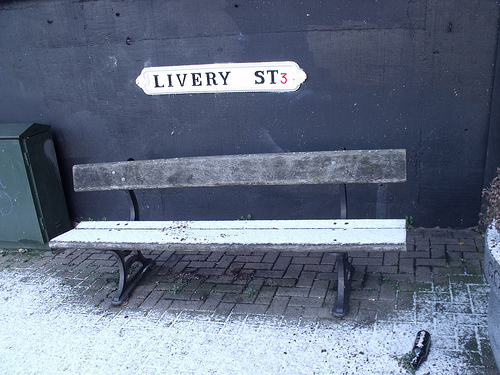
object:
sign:
[134, 59, 308, 97]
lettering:
[150, 68, 233, 90]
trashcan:
[2, 119, 72, 244]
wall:
[0, 2, 497, 240]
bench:
[47, 144, 413, 317]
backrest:
[66, 143, 413, 195]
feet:
[106, 256, 357, 321]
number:
[278, 70, 290, 90]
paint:
[108, 315, 275, 356]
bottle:
[409, 328, 431, 370]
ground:
[0, 232, 483, 373]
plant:
[476, 165, 499, 239]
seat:
[45, 218, 413, 252]